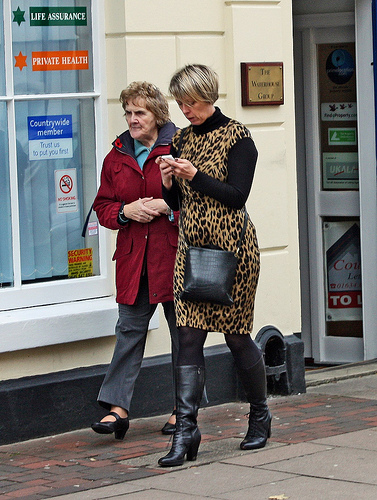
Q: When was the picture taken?
A: Daytime.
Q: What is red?
A: Woman's coat.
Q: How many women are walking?
A: Two.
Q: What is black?
A: A bag.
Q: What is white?
A: Building.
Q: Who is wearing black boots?
A: Woman on right.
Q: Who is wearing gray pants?
A: Woman on left.